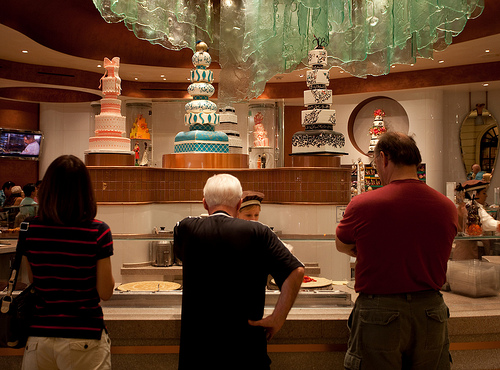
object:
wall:
[0, 106, 45, 202]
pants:
[343, 292, 453, 368]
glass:
[217, 4, 461, 79]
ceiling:
[2, 2, 497, 117]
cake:
[291, 48, 346, 153]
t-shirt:
[164, 206, 306, 365]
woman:
[11, 149, 115, 370]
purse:
[0, 217, 32, 349]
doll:
[127, 112, 152, 140]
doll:
[139, 142, 154, 166]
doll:
[130, 141, 141, 165]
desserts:
[117, 279, 184, 293]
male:
[329, 127, 462, 368]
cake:
[84, 56, 132, 151]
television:
[0, 126, 45, 161]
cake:
[171, 39, 231, 152]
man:
[169, 172, 306, 370]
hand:
[248, 312, 285, 343]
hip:
[227, 311, 268, 368]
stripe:
[95, 225, 109, 243]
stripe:
[29, 224, 99, 233]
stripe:
[25, 237, 98, 245]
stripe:
[27, 249, 97, 258]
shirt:
[18, 216, 116, 342]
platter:
[115, 279, 185, 293]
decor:
[88, 0, 489, 111]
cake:
[367, 109, 387, 152]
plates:
[270, 273, 333, 289]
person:
[235, 189, 267, 221]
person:
[17, 182, 41, 221]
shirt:
[334, 177, 464, 292]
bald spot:
[393, 129, 413, 143]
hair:
[201, 166, 244, 206]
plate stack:
[448, 255, 497, 298]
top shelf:
[161, 152, 249, 170]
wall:
[326, 86, 444, 206]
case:
[125, 99, 155, 167]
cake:
[128, 109, 150, 140]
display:
[83, 153, 354, 206]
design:
[303, 83, 334, 104]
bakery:
[0, 0, 500, 370]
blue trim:
[173, 131, 197, 155]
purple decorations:
[182, 112, 219, 126]